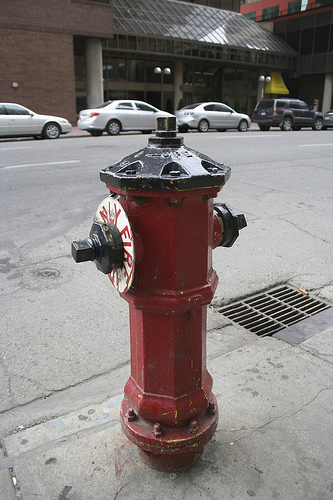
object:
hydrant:
[71, 116, 247, 471]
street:
[1, 131, 333, 500]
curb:
[0, 283, 330, 498]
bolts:
[71, 221, 125, 275]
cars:
[0, 102, 72, 140]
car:
[77, 99, 179, 136]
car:
[174, 102, 251, 132]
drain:
[209, 282, 333, 338]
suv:
[251, 98, 326, 131]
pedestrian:
[0, 122, 332, 141]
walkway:
[63, 126, 92, 135]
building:
[0, 1, 300, 129]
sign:
[94, 197, 136, 293]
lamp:
[154, 67, 162, 72]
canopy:
[265, 72, 290, 94]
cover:
[213, 282, 333, 339]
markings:
[3, 160, 81, 169]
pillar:
[85, 36, 104, 109]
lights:
[164, 68, 171, 74]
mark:
[44, 458, 57, 466]